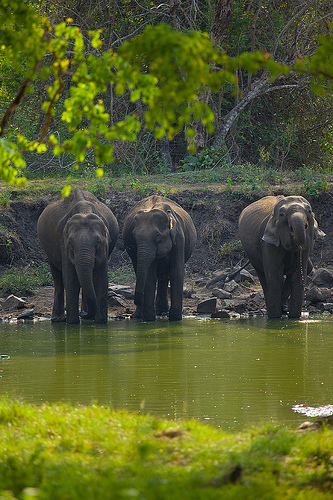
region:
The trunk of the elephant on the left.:
[66, 247, 96, 327]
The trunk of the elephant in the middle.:
[129, 238, 151, 308]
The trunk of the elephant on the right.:
[290, 218, 308, 244]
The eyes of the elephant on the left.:
[62, 233, 100, 244]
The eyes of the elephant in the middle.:
[127, 224, 166, 245]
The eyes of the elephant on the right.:
[274, 202, 317, 219]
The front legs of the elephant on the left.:
[61, 259, 115, 322]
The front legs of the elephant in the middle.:
[127, 254, 186, 321]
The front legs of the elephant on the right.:
[258, 244, 299, 311]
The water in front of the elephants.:
[7, 320, 332, 445]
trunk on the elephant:
[129, 245, 146, 305]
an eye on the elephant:
[92, 235, 104, 253]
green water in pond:
[102, 342, 246, 376]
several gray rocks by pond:
[215, 283, 251, 308]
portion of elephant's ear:
[261, 206, 276, 252]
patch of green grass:
[46, 431, 151, 471]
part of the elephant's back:
[69, 185, 84, 209]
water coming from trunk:
[298, 254, 311, 303]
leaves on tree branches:
[153, 66, 200, 112]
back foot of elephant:
[46, 312, 63, 322]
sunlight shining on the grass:
[56, 399, 133, 445]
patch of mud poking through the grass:
[147, 421, 203, 454]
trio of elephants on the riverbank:
[32, 175, 328, 338]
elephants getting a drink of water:
[27, 178, 212, 357]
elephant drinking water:
[231, 188, 330, 356]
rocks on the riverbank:
[196, 291, 228, 330]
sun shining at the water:
[110, 343, 288, 387]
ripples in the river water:
[284, 391, 330, 423]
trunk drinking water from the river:
[284, 207, 309, 254]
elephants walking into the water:
[32, 172, 320, 348]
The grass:
[89, 432, 201, 498]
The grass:
[126, 435, 195, 488]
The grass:
[139, 452, 170, 497]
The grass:
[113, 446, 154, 494]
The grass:
[85, 376, 198, 493]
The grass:
[119, 471, 153, 493]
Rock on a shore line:
[192, 296, 219, 314]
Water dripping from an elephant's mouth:
[295, 245, 309, 308]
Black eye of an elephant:
[277, 211, 286, 218]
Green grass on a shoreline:
[13, 416, 228, 488]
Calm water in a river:
[26, 357, 292, 420]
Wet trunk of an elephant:
[83, 299, 97, 319]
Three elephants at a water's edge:
[23, 190, 325, 335]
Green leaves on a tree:
[85, 31, 244, 126]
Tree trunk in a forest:
[215, 94, 260, 168]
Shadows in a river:
[5, 317, 223, 357]